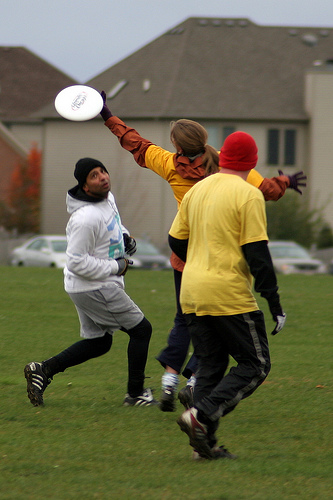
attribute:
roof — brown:
[31, 16, 330, 125]